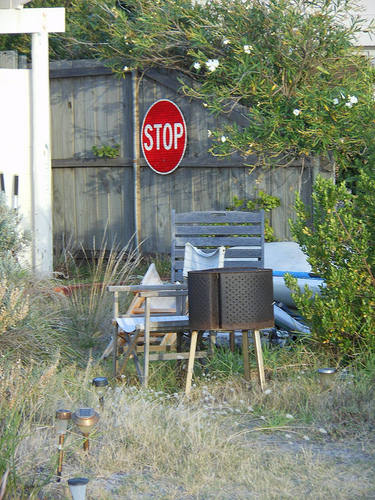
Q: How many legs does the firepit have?
A: 3.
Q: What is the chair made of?
A: Wood and Canvas.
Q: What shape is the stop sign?
A: Circle.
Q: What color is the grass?
A: Beige.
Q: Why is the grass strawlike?
A: It's dying.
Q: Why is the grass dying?
A: Needs water.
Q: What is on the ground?
A: Grass.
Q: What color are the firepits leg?
A: Tan.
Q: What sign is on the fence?
A: Stop sign.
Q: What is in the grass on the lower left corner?
A: Solar lamps.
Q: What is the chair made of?
A: Wood.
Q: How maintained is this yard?
A: Poorly maintained.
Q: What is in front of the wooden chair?
A: Grill.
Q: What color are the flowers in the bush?
A: White.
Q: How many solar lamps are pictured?
A: 5.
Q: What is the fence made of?
A: Wood.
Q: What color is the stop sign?
A: Red.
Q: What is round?
A: Stop sign.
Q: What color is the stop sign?
A: Red.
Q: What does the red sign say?
A: "STOP".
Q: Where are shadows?
A: On the shed.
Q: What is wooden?
A: A chair.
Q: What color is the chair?
A: Blue.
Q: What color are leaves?
A: Green.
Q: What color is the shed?
A: Gray.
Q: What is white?
A: Flowers.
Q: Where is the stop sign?
A: On the fence.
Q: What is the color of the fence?
A: Brown.